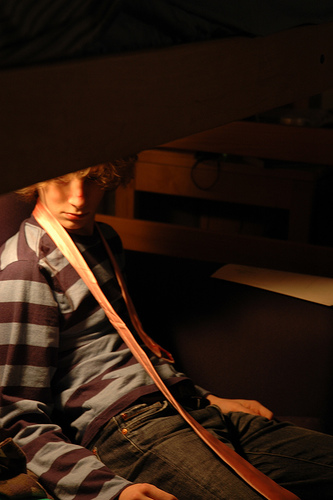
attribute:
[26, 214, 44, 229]
stripe — black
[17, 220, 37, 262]
stripe — black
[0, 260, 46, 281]
stripe — black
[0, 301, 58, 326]
stripe — black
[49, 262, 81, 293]
stripe — black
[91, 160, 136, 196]
hair — curly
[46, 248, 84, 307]
stripe — black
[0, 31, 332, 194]
plank — wood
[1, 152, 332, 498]
man — young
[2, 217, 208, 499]
shirt — long sleeved, striped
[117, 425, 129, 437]
clasp — metal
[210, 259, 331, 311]
paper — white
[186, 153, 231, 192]
circle — black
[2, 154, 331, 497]
boy — black and blue striped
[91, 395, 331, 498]
jeans — blue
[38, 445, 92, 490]
stripe — black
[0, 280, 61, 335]
stripe — black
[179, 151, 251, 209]
circle — black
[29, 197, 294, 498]
tie — brown, pink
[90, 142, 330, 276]
shelf — wooden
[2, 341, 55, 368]
stripe — black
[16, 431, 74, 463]
stripe — black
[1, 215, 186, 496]
shirt — stripes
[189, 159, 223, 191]
circle — black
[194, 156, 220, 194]
circle — black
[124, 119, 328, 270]
desk — wooden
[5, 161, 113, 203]
hair — blonde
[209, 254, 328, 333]
paper — white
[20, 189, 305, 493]
tie — brown